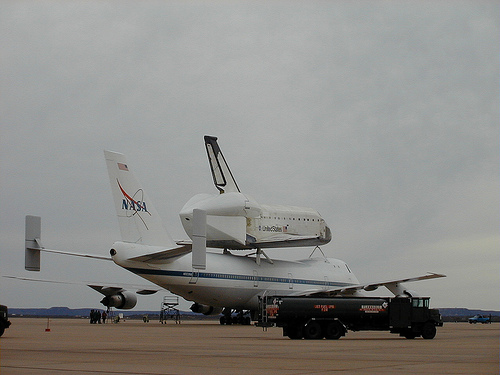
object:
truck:
[277, 293, 443, 339]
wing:
[286, 271, 447, 298]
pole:
[34, 238, 44, 249]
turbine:
[100, 292, 138, 310]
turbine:
[189, 304, 223, 316]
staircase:
[158, 292, 180, 325]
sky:
[4, 3, 499, 312]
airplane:
[17, 149, 446, 324]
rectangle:
[207, 144, 226, 186]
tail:
[202, 134, 241, 192]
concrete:
[0, 314, 500, 373]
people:
[143, 314, 146, 322]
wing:
[2, 275, 160, 289]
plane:
[177, 135, 333, 265]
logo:
[116, 178, 152, 231]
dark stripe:
[123, 267, 357, 286]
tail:
[103, 148, 174, 245]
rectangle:
[24, 215, 42, 272]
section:
[58, 42, 148, 141]